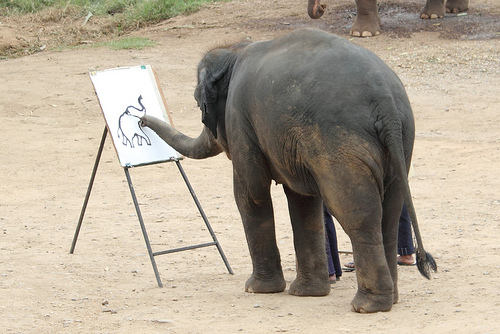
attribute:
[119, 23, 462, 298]
elephant — black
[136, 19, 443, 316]
elephant — gray, painting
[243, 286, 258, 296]
toe nails — white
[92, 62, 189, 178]
paper — white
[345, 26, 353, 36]
toe nail — white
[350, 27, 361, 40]
toe nail — white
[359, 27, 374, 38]
toe nail — white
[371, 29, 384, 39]
toe nail — white